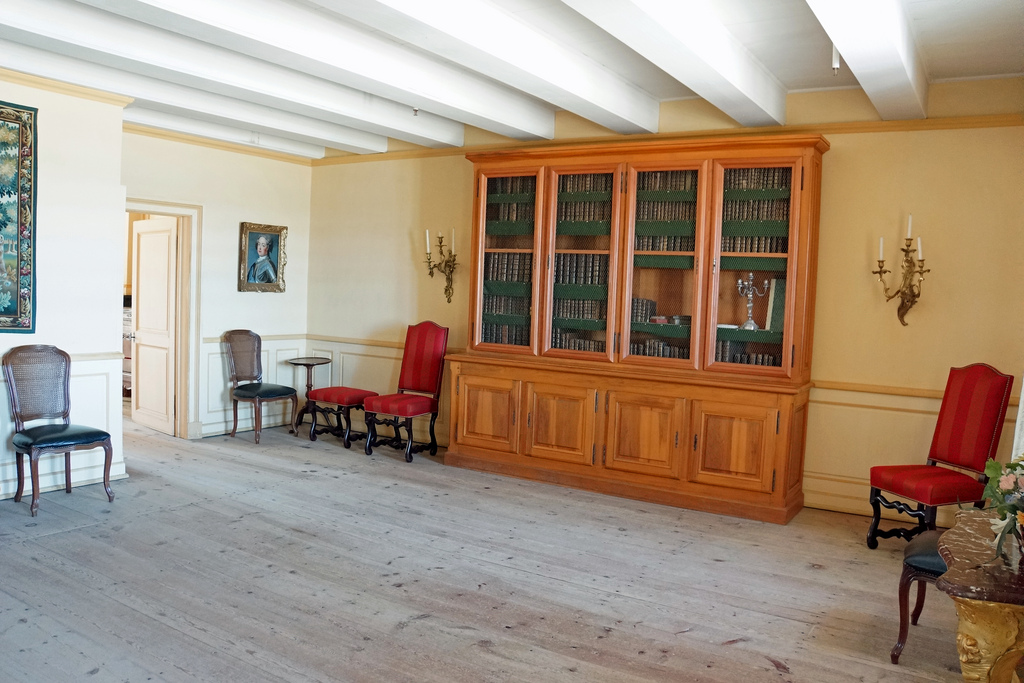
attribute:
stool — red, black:
[301, 309, 442, 459]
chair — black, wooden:
[207, 321, 326, 445]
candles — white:
[873, 212, 927, 261]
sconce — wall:
[867, 241, 929, 322]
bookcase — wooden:
[437, 130, 829, 523]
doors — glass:
[466, 146, 803, 378]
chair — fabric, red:
[361, 319, 451, 460]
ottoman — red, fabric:
[302, 382, 375, 446]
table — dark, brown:
[281, 351, 333, 435]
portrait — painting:
[235, 219, 289, 293]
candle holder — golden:
[867, 209, 932, 327]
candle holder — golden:
[418, 221, 463, 301]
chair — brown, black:
[218, 325, 298, 443]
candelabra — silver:
[730, 265, 772, 330]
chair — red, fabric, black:
[860, 360, 1016, 548]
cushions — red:
[867, 360, 1016, 506]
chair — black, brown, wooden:
[1, 342, 115, 511]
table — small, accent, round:
[279, 352, 334, 441]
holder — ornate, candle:
[728, 266, 772, 331]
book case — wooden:
[460, 148, 824, 382]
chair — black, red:
[375, 318, 451, 450]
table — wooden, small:
[289, 357, 339, 403]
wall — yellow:
[298, 158, 992, 440]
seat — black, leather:
[11, 428, 124, 455]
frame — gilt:
[237, 225, 300, 297]